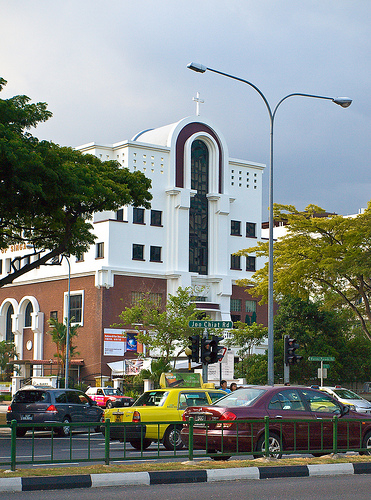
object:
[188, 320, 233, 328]
sign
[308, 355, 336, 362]
signs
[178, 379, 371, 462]
car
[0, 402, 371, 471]
street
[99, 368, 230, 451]
car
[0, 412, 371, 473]
fence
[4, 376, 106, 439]
car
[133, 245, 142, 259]
windows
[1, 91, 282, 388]
building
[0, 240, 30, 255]
writing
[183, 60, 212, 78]
lamps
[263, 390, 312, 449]
door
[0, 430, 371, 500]
ground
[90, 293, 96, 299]
bricks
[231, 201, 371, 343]
tree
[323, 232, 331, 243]
leaves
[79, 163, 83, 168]
leaves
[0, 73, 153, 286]
tree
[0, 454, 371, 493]
curb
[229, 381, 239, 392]
people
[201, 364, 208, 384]
pole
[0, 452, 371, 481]
grass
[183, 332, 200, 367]
traffic light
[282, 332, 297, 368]
traffic light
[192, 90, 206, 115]
cross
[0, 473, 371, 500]
asphalt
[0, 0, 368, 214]
sky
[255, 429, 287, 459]
wheel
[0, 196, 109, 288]
branches